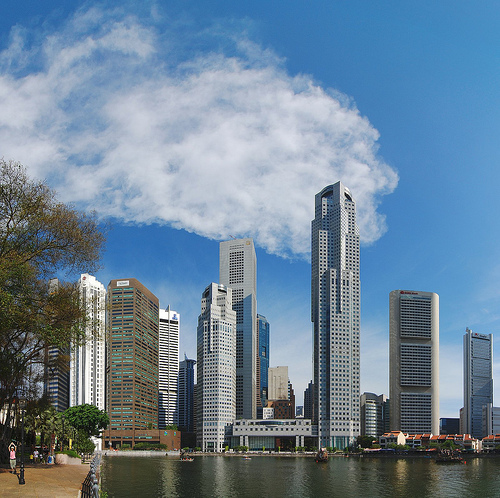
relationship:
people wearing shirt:
[7, 440, 18, 473] [7, 448, 21, 459]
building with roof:
[296, 162, 374, 449] [217, 236, 265, 248]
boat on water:
[429, 448, 481, 479] [251, 469, 368, 496]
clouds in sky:
[3, 11, 387, 269] [43, 5, 480, 166]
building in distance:
[296, 162, 374, 449] [268, 335, 334, 427]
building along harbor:
[304, 180, 361, 450] [94, 367, 449, 489]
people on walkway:
[7, 438, 64, 495] [12, 444, 99, 498]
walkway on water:
[12, 444, 99, 498] [251, 469, 368, 496]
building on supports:
[296, 162, 374, 449] [234, 431, 314, 450]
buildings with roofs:
[356, 414, 481, 458] [418, 430, 471, 442]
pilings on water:
[234, 431, 314, 450] [251, 469, 368, 496]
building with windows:
[296, 162, 374, 449] [331, 312, 346, 349]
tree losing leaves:
[3, 167, 88, 377] [46, 311, 73, 331]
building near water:
[296, 162, 374, 449] [251, 469, 368, 496]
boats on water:
[315, 439, 484, 479] [251, 469, 368, 496]